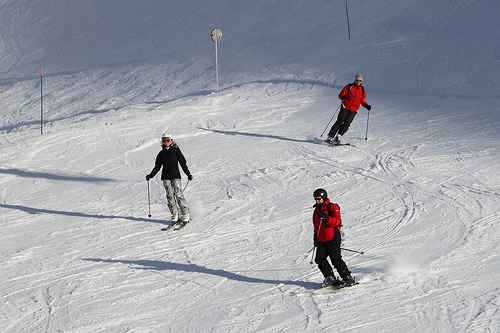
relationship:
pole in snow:
[36, 70, 47, 132] [0, 0, 500, 333]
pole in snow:
[344, 0, 353, 40] [0, 0, 500, 333]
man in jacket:
[309, 187, 358, 288] [338, 84, 369, 112]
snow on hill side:
[0, 0, 500, 333] [53, 25, 190, 162]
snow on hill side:
[0, 0, 500, 333] [0, 0, 140, 331]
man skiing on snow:
[324, 74, 373, 144] [372, 153, 499, 270]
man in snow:
[309, 187, 358, 288] [422, 150, 453, 232]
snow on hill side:
[0, 0, 500, 333] [327, 148, 496, 278]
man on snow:
[324, 74, 373, 144] [409, 20, 473, 148]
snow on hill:
[409, 20, 473, 148] [376, 19, 461, 66]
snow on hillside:
[0, 0, 500, 333] [6, 0, 146, 202]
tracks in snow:
[100, 151, 435, 301] [0, 0, 500, 333]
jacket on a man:
[319, 197, 369, 254] [301, 177, 423, 308]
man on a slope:
[324, 74, 373, 144] [387, 139, 496, 301]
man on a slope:
[309, 187, 358, 288] [387, 139, 496, 301]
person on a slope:
[144, 132, 195, 223] [387, 139, 496, 301]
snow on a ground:
[0, 0, 500, 333] [0, 0, 500, 333]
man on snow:
[309, 187, 358, 288] [297, 264, 386, 306]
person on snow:
[144, 132, 192, 222] [8, 12, 134, 319]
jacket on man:
[338, 84, 369, 112] [324, 74, 373, 144]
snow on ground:
[0, 0, 500, 333] [7, 5, 493, 321]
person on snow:
[144, 132, 195, 223] [0, 0, 500, 333]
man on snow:
[324, 74, 373, 144] [0, 0, 500, 333]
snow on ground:
[0, 0, 500, 333] [0, 0, 500, 333]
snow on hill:
[0, 0, 500, 333] [1, 2, 486, 144]